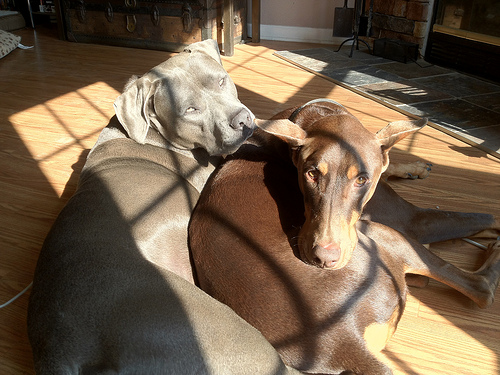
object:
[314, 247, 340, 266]
nose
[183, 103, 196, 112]
eye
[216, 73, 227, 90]
eye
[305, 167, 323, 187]
eye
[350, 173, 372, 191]
eye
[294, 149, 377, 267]
face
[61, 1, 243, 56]
chest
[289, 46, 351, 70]
tile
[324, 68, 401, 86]
tile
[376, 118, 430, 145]
ear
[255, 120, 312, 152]
ear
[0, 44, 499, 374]
wooden floor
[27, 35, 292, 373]
black dog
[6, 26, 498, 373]
floor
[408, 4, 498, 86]
fireplace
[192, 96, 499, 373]
dog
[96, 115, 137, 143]
neck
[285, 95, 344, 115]
neck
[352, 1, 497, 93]
corner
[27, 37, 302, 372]
dog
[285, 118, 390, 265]
head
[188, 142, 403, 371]
body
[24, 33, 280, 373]
bully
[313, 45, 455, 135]
shadow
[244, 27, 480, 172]
window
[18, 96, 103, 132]
rays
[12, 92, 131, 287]
shadow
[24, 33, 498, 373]
dogs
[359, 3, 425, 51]
wall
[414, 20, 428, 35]
brick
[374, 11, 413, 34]
brick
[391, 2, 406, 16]
brick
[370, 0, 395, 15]
brick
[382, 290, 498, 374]
floor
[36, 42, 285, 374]
large breed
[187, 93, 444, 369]
large breed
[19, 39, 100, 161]
hardwood floor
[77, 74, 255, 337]
light